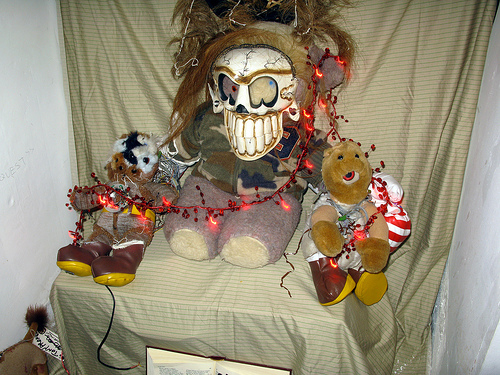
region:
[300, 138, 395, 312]
decorated plush bear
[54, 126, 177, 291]
decorated plush bear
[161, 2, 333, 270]
decorated plush bear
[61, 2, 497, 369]
beige sheet used as backdrop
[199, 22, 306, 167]
white skull decorated and painted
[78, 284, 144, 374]
exposed wiring running down table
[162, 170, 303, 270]
grey and beige plush bear feet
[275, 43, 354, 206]
red wiring going across bears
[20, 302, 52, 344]
tail of plush toy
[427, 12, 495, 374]
exposed white wall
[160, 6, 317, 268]
The teddy bear wears a mask.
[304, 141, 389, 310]
The teddy bear sits with the others.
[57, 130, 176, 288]
The teddy bear sits on the left hand side.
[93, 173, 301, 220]
Red lights are draped around the bears.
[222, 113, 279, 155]
The mask has big teeth.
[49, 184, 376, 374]
The bears sit on the table.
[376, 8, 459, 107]
The sheet is used as a back drop.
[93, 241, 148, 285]
The bear is wearing boots.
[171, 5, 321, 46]
The mask has crazy hair.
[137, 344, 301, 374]
A book is propped on the table.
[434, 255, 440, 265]
part of a curtain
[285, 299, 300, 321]
edge of a board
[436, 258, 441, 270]
edge of a curtain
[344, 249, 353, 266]
edge of a doll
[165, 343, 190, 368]
part of a board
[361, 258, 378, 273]
part of a sweater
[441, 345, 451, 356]
edge of a wall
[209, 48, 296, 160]
a skeleton mask with big teeth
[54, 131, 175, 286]
teddy bear for a ghoul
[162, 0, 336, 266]
teddy bear with heavy make-up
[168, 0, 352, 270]
teddy bear wearing a mask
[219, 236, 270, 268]
the foot of a teddy bear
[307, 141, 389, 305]
a feminine looking stuffed animal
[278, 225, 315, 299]
a chain or ribbon on the surface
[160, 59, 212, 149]
tufts of hair on the mask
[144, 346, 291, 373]
an open book below the creature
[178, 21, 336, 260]
purple teddy bear wearing a mask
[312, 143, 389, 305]
teddy bear with one eye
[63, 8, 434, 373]
sheet draped on table and behind table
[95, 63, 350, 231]
string of red lights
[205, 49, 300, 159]
white skeleton mask with large teeth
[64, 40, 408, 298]
decorated teddy bears on the table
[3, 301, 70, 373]
stuffed animal on the floor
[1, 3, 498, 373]
white walls surrounding the table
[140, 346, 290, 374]
sign leaning on sheet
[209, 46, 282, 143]
hideous mask of colors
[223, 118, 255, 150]
ugly mask of horror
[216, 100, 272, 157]
ugly mask smiling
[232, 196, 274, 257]
left leg of the teddy bear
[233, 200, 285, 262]
purple lef leg teddy bear